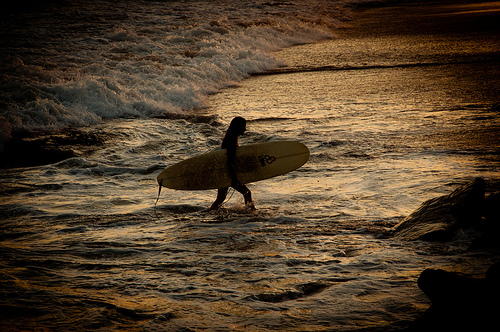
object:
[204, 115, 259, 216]
person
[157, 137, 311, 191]
surfing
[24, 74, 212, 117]
waves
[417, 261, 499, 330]
rocks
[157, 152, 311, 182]
stringer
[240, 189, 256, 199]
knees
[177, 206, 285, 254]
water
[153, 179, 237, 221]
strap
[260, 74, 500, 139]
water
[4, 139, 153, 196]
water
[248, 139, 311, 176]
board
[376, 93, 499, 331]
shoreline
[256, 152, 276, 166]
logo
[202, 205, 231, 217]
feet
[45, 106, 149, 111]
bubbles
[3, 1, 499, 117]
ocean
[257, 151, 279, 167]
design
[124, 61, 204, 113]
foam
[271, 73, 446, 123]
light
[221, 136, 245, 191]
arm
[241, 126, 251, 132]
nose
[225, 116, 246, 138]
profile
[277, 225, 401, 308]
ripples